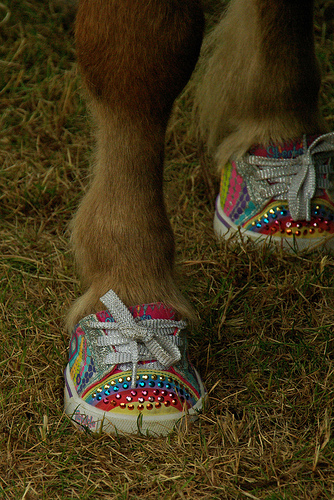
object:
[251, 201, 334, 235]
rainbow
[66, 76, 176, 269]
calf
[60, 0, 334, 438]
ungulate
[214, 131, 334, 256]
shoe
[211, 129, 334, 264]
front foot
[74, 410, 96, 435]
word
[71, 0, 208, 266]
fur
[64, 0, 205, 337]
leg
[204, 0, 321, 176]
leg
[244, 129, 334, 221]
laces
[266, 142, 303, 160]
word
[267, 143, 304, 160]
text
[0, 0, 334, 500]
grass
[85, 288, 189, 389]
laces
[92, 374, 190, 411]
gemstones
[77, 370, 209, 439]
toe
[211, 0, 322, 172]
fur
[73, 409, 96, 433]
text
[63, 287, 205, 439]
shoe